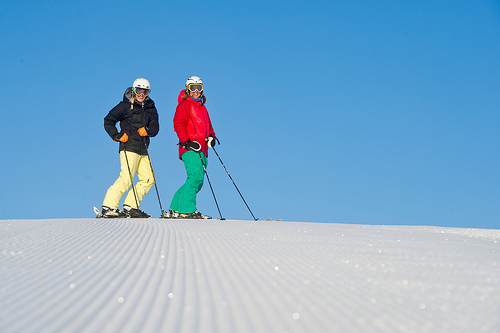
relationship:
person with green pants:
[170, 76, 218, 214] [170, 149, 207, 216]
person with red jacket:
[170, 76, 218, 214] [172, 89, 214, 160]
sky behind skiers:
[6, 7, 497, 132] [73, 54, 257, 221]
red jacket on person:
[172, 89, 214, 160] [170, 76, 218, 214]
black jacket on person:
[101, 96, 164, 151] [102, 78, 159, 209]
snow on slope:
[1, 217, 499, 331] [2, 214, 496, 329]